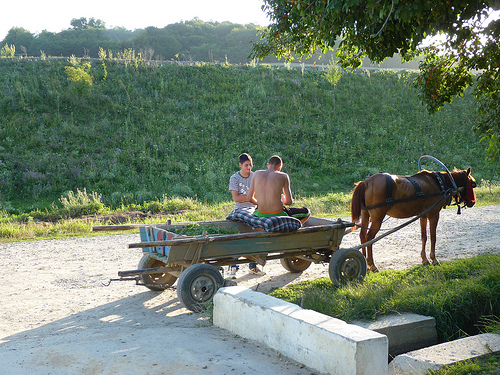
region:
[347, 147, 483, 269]
A brown horse on a harness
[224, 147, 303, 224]
two young men talking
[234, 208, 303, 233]
a checkered cushion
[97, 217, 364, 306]
a wooden cart with wheels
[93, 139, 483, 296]
a horse pulling a wooden cart with a young man in it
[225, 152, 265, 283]
A boy standing by the cart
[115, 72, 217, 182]
a grassy hill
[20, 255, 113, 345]
a graveled road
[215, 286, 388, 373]
a stone ledge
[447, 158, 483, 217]
The side view of a horses face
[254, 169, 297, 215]
the man is shirtless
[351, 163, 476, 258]
the horse is brown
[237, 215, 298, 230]
the blanket is black and white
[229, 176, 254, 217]
the shirt is grey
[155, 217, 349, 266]
grass is in the cart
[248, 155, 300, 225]
the boy is wearing shorts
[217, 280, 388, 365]
the stone is made of cement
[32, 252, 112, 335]
the ground is unpaved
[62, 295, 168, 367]
shadows are on the ground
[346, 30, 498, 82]
sunlight is shining behind the trees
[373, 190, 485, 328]
the horse is brown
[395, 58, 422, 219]
the horse is brown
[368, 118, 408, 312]
the horse is brown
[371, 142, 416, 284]
the horse is brown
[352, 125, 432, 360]
the horse is brown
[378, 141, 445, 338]
the horse is brown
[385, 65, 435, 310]
the horse is brown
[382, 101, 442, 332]
the horse is brown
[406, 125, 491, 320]
the horse is brown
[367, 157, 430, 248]
the horse is brown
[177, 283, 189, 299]
the wheel is black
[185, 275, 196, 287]
the wheel is black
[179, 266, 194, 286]
the wheel is black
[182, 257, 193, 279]
the wheel is black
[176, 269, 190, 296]
the wheel is black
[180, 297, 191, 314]
the wheel is black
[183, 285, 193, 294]
the wheel is black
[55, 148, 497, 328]
horse hooked up to a wagon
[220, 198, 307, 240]
black and white checkered pillow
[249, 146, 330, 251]
man sitting on the wagon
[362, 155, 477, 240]
a horse with its ribs sticking out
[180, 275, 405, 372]
white cement block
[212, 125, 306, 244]
two people talking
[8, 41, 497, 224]
a steap grassy hill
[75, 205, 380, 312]
wood wagon on wheels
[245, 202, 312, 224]
black shorts with a green stripe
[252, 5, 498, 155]
green leafs from a tree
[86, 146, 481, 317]
horse pulling wooden cart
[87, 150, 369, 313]
two people in back of wooden cart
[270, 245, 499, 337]
patch of grass next to horse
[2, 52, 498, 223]
grass covered hill next to horse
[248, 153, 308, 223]
a shirtless young man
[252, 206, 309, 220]
a green and black striped pair of board shorts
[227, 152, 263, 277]
a standing young man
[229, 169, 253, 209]
a grey t-shirt